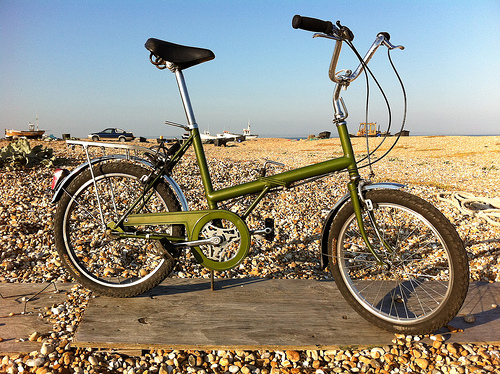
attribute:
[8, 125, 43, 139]
sailboat — big , brown 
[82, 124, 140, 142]
car — blue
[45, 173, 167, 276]
wheel — rear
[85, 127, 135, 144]
blue car — small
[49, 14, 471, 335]
bike — green, small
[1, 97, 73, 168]
sailboat — white , brown 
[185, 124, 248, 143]
sailboat — far, brown-and-white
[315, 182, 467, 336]
wheel — frontal